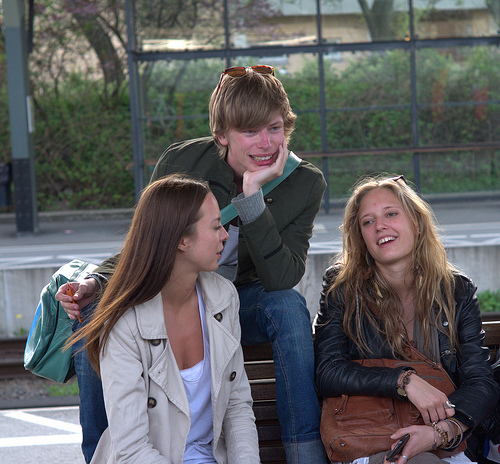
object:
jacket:
[310, 263, 499, 453]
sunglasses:
[216, 65, 279, 79]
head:
[206, 66, 296, 177]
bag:
[318, 259, 464, 462]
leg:
[238, 289, 329, 462]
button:
[227, 370, 236, 381]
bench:
[87, 312, 499, 463]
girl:
[86, 173, 261, 461]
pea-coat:
[92, 271, 261, 462]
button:
[213, 312, 221, 321]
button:
[140, 370, 151, 379]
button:
[146, 398, 158, 409]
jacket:
[84, 136, 328, 302]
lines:
[0, 409, 86, 435]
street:
[0, 198, 499, 269]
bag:
[22, 150, 302, 385]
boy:
[54, 66, 326, 463]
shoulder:
[284, 150, 326, 205]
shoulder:
[151, 135, 213, 182]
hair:
[315, 172, 463, 363]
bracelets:
[429, 417, 465, 452]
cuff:
[230, 188, 267, 227]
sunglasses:
[356, 173, 411, 189]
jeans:
[73, 286, 328, 462]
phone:
[385, 432, 410, 462]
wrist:
[428, 420, 457, 449]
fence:
[125, 0, 500, 214]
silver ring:
[444, 402, 457, 413]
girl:
[312, 171, 500, 462]